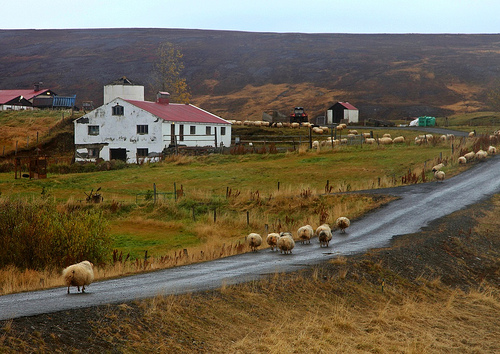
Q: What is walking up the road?
A: Sheep.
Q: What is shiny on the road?
A: Water.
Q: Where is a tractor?
A: Middle back.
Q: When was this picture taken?
A: Daytime.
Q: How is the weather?
A: Gloomy.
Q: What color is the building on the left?
A: White.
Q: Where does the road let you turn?
A: The middle before white barn.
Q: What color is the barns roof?
A: Red.